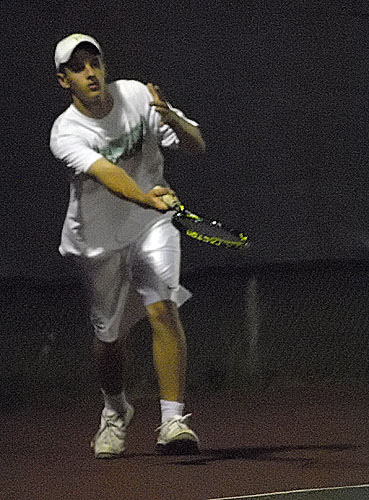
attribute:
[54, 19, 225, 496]
player — tennis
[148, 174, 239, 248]
racket — tennis, black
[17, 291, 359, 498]
court — tennis, red, white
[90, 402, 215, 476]
shoe — white, lace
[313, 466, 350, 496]
line — white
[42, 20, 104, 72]
hat — white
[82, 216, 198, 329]
short — white, nike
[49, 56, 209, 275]
shirt — white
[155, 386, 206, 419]
sock — white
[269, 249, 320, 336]
fence — black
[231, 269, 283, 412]
pole — grey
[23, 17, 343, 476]
photo — grainy